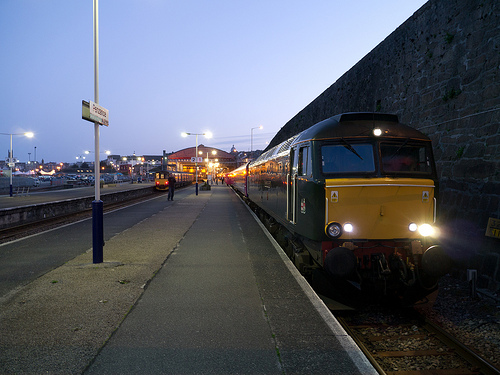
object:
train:
[226, 113, 447, 298]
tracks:
[339, 308, 391, 373]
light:
[369, 126, 385, 139]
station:
[169, 142, 232, 182]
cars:
[230, 160, 253, 199]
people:
[220, 175, 226, 185]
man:
[166, 173, 178, 203]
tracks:
[0, 191, 162, 238]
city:
[0, 145, 234, 179]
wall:
[256, 0, 500, 331]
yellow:
[324, 178, 435, 240]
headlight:
[325, 221, 343, 239]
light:
[342, 221, 355, 234]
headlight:
[418, 221, 435, 238]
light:
[406, 222, 418, 233]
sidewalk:
[0, 178, 381, 374]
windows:
[320, 145, 376, 174]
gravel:
[312, 291, 500, 373]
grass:
[199, 182, 211, 191]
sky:
[0, 0, 431, 164]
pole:
[88, 1, 106, 266]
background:
[7, 151, 234, 188]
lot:
[32, 175, 126, 189]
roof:
[167, 143, 236, 160]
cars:
[42, 174, 52, 182]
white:
[80, 99, 111, 125]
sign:
[79, 98, 110, 128]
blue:
[83, 97, 109, 125]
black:
[231, 108, 444, 250]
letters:
[92, 104, 97, 114]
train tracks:
[416, 301, 499, 374]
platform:
[0, 180, 383, 374]